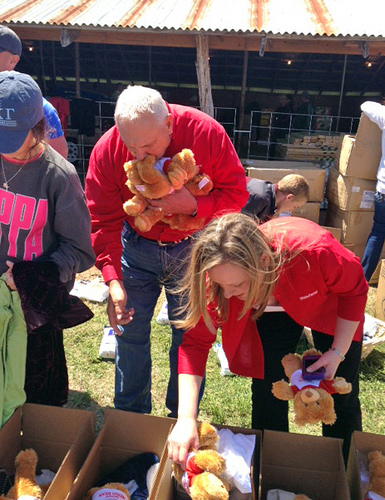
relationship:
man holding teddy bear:
[78, 83, 232, 417] [120, 176, 230, 225]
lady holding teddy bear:
[166, 213, 370, 487] [274, 348, 346, 425]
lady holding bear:
[166, 213, 370, 487] [170, 417, 232, 499]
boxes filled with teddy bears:
[32, 396, 318, 498] [49, 429, 271, 495]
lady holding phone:
[168, 213, 369, 470] [302, 354, 325, 380]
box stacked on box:
[334, 209, 377, 248] [329, 179, 376, 211]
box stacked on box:
[329, 179, 376, 211] [335, 140, 372, 180]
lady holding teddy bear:
[166, 213, 370, 487] [270, 348, 353, 427]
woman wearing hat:
[1, 68, 101, 415] [1, 69, 49, 154]